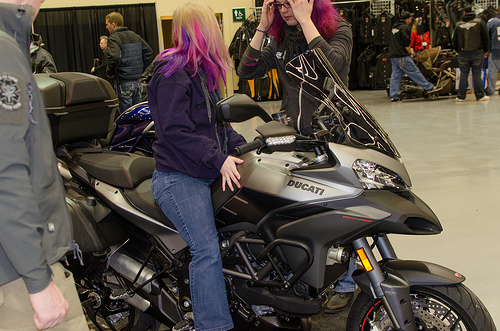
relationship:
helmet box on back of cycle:
[33, 68, 123, 149] [34, 57, 481, 305]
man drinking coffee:
[103, 10, 154, 115] [98, 33, 107, 46]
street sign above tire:
[355, 245, 375, 272] [344, 282, 500, 330]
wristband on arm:
[252, 24, 269, 44] [245, 18, 272, 39]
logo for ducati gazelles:
[277, 175, 326, 196] [283, 173, 327, 202]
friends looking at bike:
[142, 1, 250, 331] [36, 44, 463, 329]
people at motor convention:
[355, 9, 497, 101] [0, 0, 480, 326]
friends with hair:
[142, 1, 250, 331] [149, 0, 238, 86]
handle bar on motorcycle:
[232, 115, 330, 163] [33, 46, 496, 328]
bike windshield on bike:
[283, 48, 400, 159] [50, 78, 495, 330]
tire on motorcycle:
[334, 260, 462, 322] [89, 75, 494, 325]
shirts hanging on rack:
[355, 5, 405, 90] [336, 0, 399, 92]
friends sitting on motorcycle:
[142, 1, 250, 331] [33, 46, 496, 328]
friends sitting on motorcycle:
[142, 1, 250, 331] [58, 71, 498, 319]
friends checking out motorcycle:
[246, 0, 373, 130] [89, 75, 494, 325]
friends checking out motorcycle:
[138, 3, 254, 329] [89, 75, 494, 325]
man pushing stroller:
[385, 11, 443, 103] [409, 42, 464, 102]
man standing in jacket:
[447, 3, 491, 106] [450, 17, 492, 56]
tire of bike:
[344, 282, 500, 330] [36, 44, 463, 329]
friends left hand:
[142, 1, 250, 331] [215, 147, 252, 201]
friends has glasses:
[236, 0, 356, 129] [270, 0, 296, 10]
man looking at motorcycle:
[72, 17, 159, 120] [33, 46, 496, 328]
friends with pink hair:
[142, 1, 250, 331] [154, 14, 243, 90]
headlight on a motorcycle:
[341, 157, 413, 213] [37, 74, 460, 328]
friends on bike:
[142, 1, 250, 331] [36, 44, 463, 329]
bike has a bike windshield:
[77, 75, 442, 324] [283, 48, 400, 159]